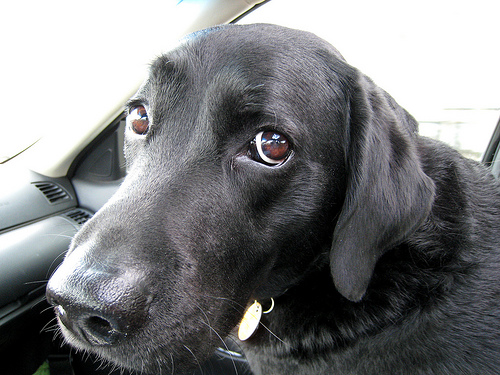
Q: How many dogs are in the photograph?
A: One.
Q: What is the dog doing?
A: Looking.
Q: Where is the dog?
A: In an automobile.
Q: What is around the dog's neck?
A: A collar.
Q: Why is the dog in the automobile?
A: To ride.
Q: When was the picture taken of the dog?
A: Daytime.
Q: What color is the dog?
A: Black.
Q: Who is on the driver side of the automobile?
A: A person.